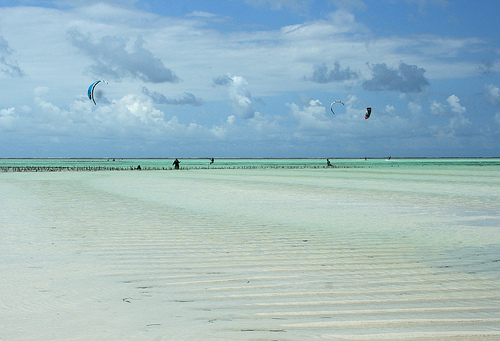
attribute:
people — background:
[168, 155, 182, 171]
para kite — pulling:
[84, 78, 108, 108]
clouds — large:
[94, 27, 429, 154]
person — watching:
[171, 156, 180, 170]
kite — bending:
[326, 96, 347, 118]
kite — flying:
[70, 73, 152, 117]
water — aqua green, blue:
[21, 154, 467, 179]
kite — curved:
[321, 93, 352, 126]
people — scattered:
[166, 151, 338, 171]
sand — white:
[2, 164, 498, 339]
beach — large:
[2, 161, 499, 339]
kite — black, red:
[358, 105, 375, 119]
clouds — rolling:
[0, 9, 499, 157]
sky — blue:
[385, 69, 441, 107]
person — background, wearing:
[322, 156, 336, 168]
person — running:
[318, 152, 340, 177]